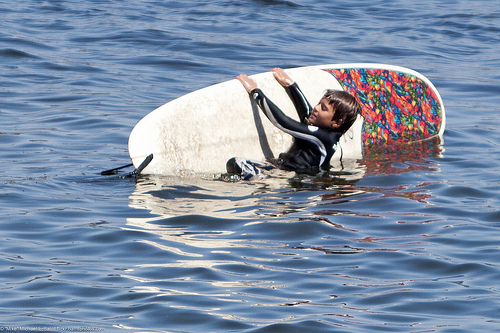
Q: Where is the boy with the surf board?
A: In the water.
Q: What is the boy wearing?
A: A wet suit.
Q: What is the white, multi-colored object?
A: A surf board.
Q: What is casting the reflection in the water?
A: The surf board.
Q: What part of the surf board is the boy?
A: The white.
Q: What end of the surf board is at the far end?
A: The bright colored part.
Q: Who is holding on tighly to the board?
A: A boy.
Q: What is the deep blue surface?
A: Water.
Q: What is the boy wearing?
A: A wet suit.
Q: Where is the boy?
A: In the water.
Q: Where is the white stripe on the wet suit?
A: On the arm.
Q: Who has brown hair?
A: The boy.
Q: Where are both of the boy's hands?
A: On the edge of the board.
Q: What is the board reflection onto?
A: The water.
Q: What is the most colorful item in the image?
A: The surfboard.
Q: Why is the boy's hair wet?
A: He is in the water.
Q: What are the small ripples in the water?
A: Waves.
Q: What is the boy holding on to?
A: A surfboard.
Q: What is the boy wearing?
A: A wetsuit.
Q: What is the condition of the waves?
A: The water is calm.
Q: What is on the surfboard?
A: A colorful pattern.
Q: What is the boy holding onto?
A: A white surfboard.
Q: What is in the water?
A: A surfboard.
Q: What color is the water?
A: Blue.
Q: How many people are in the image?
A: One.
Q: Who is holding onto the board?
A: A kid.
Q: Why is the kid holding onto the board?
A: To climb up.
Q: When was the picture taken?
A: At daytime.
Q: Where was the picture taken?
A: The ocean.